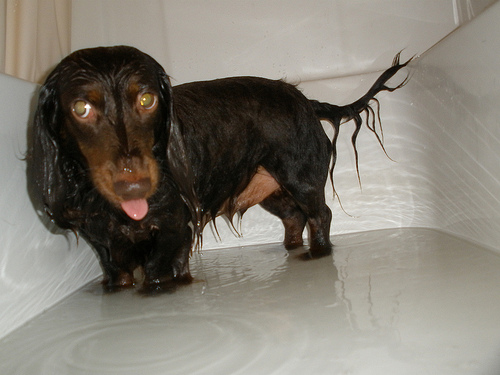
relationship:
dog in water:
[23, 41, 413, 293] [8, 223, 498, 371]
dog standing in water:
[26, 45, 419, 298] [97, 264, 444, 370]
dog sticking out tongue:
[26, 45, 419, 298] [120, 199, 152, 224]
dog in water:
[23, 41, 413, 293] [197, 271, 458, 358]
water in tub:
[168, 251, 395, 363] [8, 6, 482, 362]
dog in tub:
[26, 45, 419, 298] [8, 6, 482, 362]